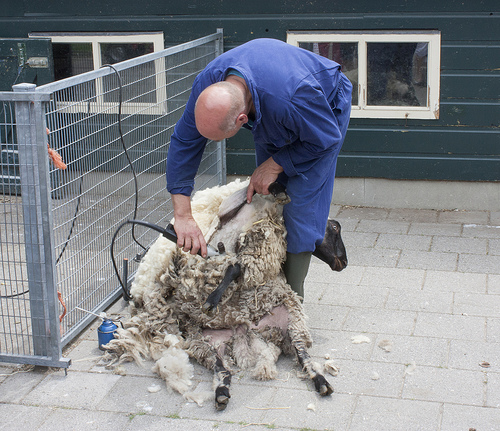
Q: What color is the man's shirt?
A: Blue.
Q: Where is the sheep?
A: Outside the building.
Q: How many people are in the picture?
A: One.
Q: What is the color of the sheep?
A: Black and white.